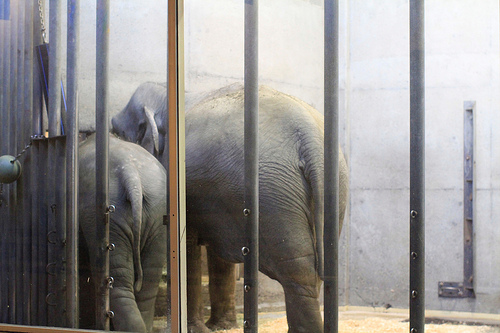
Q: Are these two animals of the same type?
A: Yes, all the animals are elephants.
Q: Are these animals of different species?
A: No, all the animals are elephants.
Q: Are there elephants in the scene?
A: Yes, there is an elephant.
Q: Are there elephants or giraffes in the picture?
A: Yes, there is an elephant.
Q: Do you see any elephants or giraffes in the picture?
A: Yes, there is an elephant.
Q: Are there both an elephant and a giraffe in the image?
A: No, there is an elephant but no giraffes.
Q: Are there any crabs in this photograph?
A: No, there are no crabs.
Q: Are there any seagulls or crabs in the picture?
A: No, there are no crabs or seagulls.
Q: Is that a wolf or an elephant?
A: That is an elephant.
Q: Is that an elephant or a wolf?
A: That is an elephant.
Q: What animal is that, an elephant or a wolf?
A: That is an elephant.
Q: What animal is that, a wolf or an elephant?
A: That is an elephant.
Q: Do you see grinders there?
A: No, there are no grinders.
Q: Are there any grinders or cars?
A: No, there are no grinders or cars.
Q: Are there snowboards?
A: No, there are no snowboards.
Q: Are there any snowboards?
A: No, there are no snowboards.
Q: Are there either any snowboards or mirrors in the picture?
A: No, there are no snowboards or mirrors.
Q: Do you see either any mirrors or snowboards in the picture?
A: No, there are no snowboards or mirrors.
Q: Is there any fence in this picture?
A: Yes, there is a fence.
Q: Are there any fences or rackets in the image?
A: Yes, there is a fence.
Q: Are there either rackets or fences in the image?
A: Yes, there is a fence.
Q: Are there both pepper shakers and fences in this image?
A: No, there is a fence but no pepper shakers.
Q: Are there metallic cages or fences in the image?
A: Yes, there is a metal fence.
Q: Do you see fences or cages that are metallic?
A: Yes, the fence is metallic.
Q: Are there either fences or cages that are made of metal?
A: Yes, the fence is made of metal.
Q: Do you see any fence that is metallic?
A: Yes, there is a metal fence.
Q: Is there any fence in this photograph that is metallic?
A: Yes, there is a fence that is metallic.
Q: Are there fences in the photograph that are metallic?
A: Yes, there is a fence that is metallic.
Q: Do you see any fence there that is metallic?
A: Yes, there is a fence that is metallic.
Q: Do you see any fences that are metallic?
A: Yes, there is a fence that is metallic.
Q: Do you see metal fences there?
A: Yes, there is a fence that is made of metal.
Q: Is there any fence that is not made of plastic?
A: Yes, there is a fence that is made of metal.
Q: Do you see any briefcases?
A: No, there are no briefcases.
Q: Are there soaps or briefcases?
A: No, there are no briefcases or soaps.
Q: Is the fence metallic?
A: Yes, the fence is metallic.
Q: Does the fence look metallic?
A: Yes, the fence is metallic.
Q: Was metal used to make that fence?
A: Yes, the fence is made of metal.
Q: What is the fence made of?
A: The fence is made of metal.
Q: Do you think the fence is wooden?
A: No, the fence is metallic.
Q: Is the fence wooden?
A: No, the fence is metallic.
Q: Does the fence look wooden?
A: No, the fence is metallic.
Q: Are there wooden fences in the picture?
A: No, there is a fence but it is metallic.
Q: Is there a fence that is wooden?
A: No, there is a fence but it is metallic.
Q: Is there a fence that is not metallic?
A: No, there is a fence but it is metallic.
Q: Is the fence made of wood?
A: No, the fence is made of metal.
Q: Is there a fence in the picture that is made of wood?
A: No, there is a fence but it is made of metal.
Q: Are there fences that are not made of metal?
A: No, there is a fence but it is made of metal.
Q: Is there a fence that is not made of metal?
A: No, there is a fence but it is made of metal.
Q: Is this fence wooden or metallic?
A: The fence is metallic.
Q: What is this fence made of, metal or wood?
A: The fence is made of metal.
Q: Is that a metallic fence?
A: Yes, that is a metallic fence.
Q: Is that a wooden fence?
A: No, that is a metallic fence.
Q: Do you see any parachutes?
A: No, there are no parachutes.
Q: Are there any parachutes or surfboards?
A: No, there are no parachutes or surfboards.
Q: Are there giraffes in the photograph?
A: No, there are no giraffes.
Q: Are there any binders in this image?
A: No, there are no binders.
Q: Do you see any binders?
A: No, there are no binders.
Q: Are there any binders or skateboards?
A: No, there are no binders or skateboards.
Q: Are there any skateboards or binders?
A: No, there are no binders or skateboards.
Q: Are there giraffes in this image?
A: No, there are no giraffes.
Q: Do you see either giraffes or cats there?
A: No, there are no giraffes or cats.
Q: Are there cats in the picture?
A: No, there are no cats.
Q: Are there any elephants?
A: Yes, there is an elephant.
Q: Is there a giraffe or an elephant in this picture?
A: Yes, there is an elephant.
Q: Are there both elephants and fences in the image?
A: Yes, there are both an elephant and a fence.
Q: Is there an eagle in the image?
A: No, there are no eagles.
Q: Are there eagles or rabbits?
A: No, there are no eagles or rabbits.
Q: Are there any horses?
A: No, there are no horses.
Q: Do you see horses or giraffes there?
A: No, there are no horses or giraffes.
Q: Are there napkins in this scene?
A: No, there are no napkins.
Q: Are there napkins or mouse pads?
A: No, there are no napkins or mouse pads.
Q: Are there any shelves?
A: No, there are no shelves.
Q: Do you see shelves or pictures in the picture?
A: No, there are no shelves or pictures.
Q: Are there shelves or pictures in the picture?
A: No, there are no shelves or pictures.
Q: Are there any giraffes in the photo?
A: No, there are no giraffes.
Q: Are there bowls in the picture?
A: No, there are no bowls.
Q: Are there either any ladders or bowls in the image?
A: No, there are no bowls or ladders.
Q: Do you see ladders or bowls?
A: No, there are no bowls or ladders.